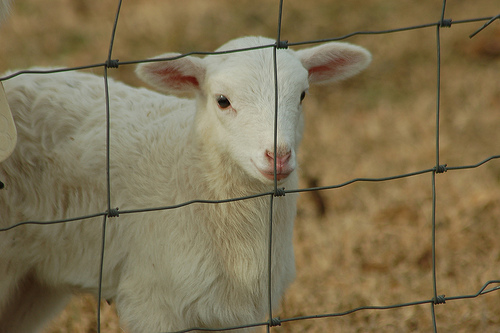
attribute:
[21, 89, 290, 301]
lamb — white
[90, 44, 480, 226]
fence — wire, wired, joint, metal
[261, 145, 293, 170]
nose — pink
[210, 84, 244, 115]
eye — black, rounded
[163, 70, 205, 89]
ear — pink, white, tiny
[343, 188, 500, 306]
grass — brown, enclosed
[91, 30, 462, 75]
wire — black, metal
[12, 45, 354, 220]
sheep — white, looking, body, baby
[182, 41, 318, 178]
head — white, little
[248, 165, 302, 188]
mouth — pink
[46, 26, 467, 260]
pen — wire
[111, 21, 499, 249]
field — yellow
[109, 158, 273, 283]
fur — white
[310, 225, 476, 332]
ground — brown